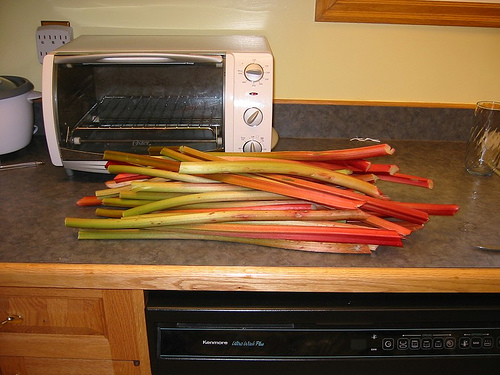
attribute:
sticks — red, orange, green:
[58, 137, 462, 257]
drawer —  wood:
[3, 261, 499, 371]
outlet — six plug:
[33, 26, 70, 68]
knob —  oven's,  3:
[243, 62, 270, 82]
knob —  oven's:
[241, 105, 260, 120]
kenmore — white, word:
[202, 337, 232, 350]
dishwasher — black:
[143, 291, 497, 373]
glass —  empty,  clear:
[446, 98, 498, 171]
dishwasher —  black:
[65, 275, 497, 367]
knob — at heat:
[234, 57, 273, 88]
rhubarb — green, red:
[64, 142, 462, 258]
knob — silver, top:
[242, 57, 266, 85]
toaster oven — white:
[37, 32, 274, 183]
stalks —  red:
[98, 145, 392, 187]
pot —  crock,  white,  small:
[1, 74, 41, 157]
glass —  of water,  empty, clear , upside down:
[461, 100, 499, 175]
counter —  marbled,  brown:
[4, 125, 499, 265]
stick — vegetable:
[190, 146, 394, 165]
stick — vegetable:
[179, 162, 386, 194]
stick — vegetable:
[59, 206, 373, 231]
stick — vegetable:
[77, 226, 402, 240]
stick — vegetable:
[108, 172, 462, 213]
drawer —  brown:
[1, 291, 136, 363]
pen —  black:
[0, 155, 50, 174]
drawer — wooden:
[3, 285, 133, 360]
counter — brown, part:
[5, 253, 429, 295]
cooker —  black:
[105, 65, 145, 90]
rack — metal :
[80, 90, 215, 135]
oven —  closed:
[42, 32, 272, 162]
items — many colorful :
[72, 141, 451, 261]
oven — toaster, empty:
[39, 30, 283, 176]